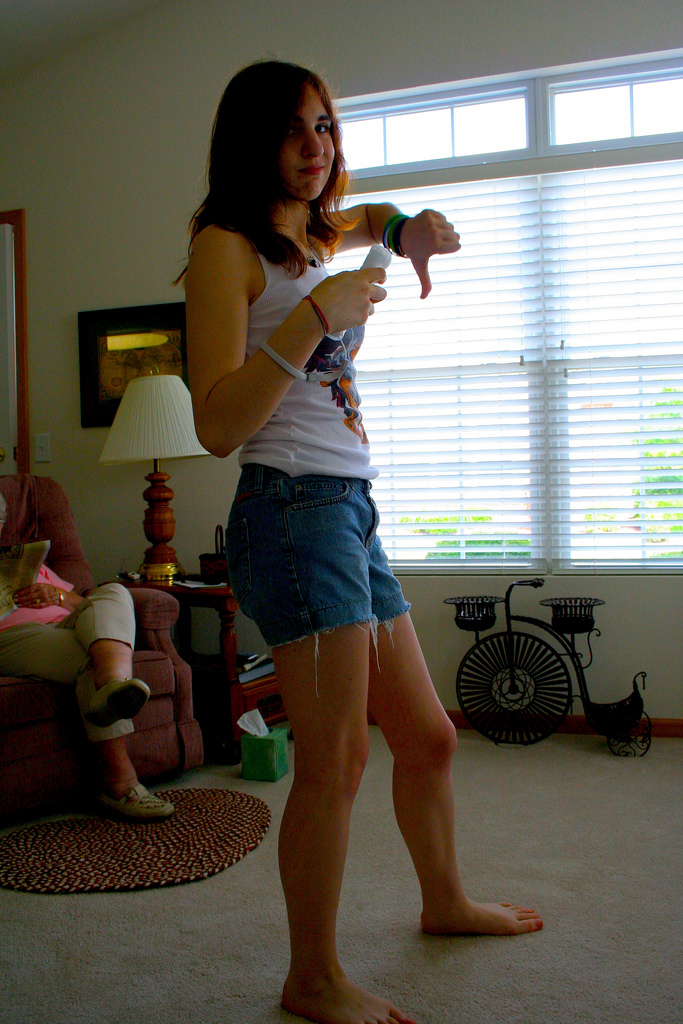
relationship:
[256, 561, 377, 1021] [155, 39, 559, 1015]
leg of woman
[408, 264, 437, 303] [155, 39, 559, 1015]
thumb of woman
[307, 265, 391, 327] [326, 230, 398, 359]
hand holds wii remote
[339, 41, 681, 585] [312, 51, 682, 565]
blinds over window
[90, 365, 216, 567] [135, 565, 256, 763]
lamp on table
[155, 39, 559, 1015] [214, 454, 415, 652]
woman wears shorts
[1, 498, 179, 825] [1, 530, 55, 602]
woman reads newspaper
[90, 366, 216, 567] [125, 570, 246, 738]
lamp on table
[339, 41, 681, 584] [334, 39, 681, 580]
blinds on window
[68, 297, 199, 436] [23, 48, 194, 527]
artwork on wall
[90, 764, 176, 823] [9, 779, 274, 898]
foot on rug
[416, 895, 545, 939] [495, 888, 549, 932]
foot has toes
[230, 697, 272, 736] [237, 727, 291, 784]
tissue in box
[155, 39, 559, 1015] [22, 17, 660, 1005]
woman standing in living room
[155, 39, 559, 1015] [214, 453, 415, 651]
woman wearing shorts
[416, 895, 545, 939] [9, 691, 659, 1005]
foot on carpet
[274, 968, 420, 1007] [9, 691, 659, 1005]
foot on carpet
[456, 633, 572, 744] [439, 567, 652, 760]
wheel belongs to cart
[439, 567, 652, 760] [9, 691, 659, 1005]
cart on carpet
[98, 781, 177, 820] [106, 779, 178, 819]
shoe worn on foot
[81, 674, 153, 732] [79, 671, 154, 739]
shoe worn on foot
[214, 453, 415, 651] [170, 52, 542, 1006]
shorts worn by human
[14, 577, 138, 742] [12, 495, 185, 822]
pants worn by human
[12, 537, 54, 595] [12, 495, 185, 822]
newspaper held by human